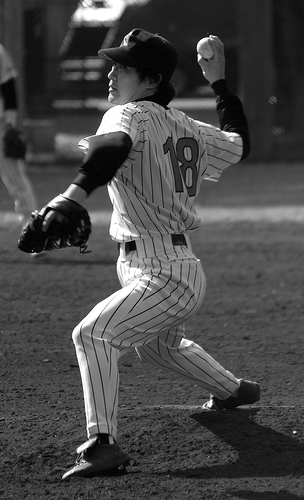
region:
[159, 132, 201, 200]
Number 18 on back of uniform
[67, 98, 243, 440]
Stripes on a uniform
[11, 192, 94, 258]
A black leather glove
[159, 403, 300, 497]
Shadows on the dirt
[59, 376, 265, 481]
A pair of sneakers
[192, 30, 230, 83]
Baseball in a hand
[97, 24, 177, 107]
Hat on man's head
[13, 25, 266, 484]
A pitcher throwing the ball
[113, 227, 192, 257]
Belt around a waist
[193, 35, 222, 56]
Baseball is white and round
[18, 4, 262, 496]
Man is a baseball player.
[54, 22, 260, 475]
Baseball player is a pitcher.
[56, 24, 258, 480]
Pitcher ready to throw the ball.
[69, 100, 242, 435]
Pitcher wearing a striped baseball suit.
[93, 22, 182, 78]
Pitcher wearing a black cap.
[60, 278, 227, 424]
Pitcher bending his knees.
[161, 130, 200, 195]
Pitcher is baseball player number 18.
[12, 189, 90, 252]
Pitcher wearing a black leather glove.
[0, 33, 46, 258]
Another baseball player standing aside.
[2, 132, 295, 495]
Baseball player is on a baseball field.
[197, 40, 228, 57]
Player holding a baseball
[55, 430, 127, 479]
man wearing black cleats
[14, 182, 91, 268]
player holding a glove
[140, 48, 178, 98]
man with black hair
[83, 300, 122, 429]
man wearing pinstriped pants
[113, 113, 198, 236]
Man wearing a jersey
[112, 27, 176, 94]
player wearing a black hat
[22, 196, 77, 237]
player with a black glove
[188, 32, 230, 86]
Man throwing a pitch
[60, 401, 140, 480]
cleats in the dirt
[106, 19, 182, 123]
the head of a man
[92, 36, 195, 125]
a man with a cap on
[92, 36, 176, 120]
the face of a man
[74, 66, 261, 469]
a man with a uniform on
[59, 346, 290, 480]
a man with shoes on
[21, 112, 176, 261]
a man wearing a baseball glove on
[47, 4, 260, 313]
a man throwing a baseball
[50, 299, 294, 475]
a man standing on dirt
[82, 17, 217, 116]
a man wearing a black hat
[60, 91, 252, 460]
a man with a striped uniform on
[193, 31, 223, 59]
white baseball with stitches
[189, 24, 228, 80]
white baseball in right hand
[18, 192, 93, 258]
baseball glove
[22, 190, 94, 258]
baseball glove in left hand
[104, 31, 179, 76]
person wearing baseball cap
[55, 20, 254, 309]
baseball player ready to throw a ball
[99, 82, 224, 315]
person wearing striped uniform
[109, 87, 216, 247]
striped baseball uniform shirt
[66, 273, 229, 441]
striped baseball uniform pants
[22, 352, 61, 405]
dry dirt